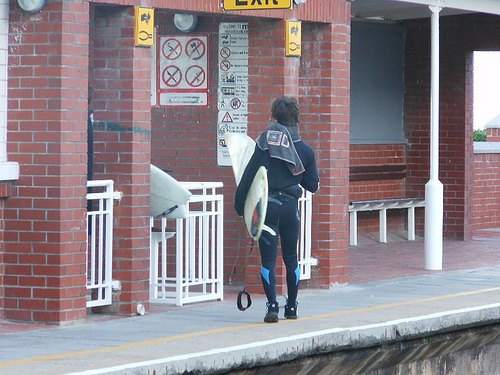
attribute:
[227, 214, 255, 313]
cord — on the surfboard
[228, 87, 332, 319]
man — next to bricks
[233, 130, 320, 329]
wetsuit — blue, black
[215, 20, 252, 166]
sign — next to bricks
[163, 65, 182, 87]
sign — next to bricks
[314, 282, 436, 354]
platform — stone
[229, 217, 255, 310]
rope — on the man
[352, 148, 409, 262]
bench — white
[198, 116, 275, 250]
surf board — with the man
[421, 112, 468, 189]
ground — next to bricks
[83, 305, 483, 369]
line — on the ground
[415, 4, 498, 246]
pillar — supporting, white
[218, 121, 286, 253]
surfboard — white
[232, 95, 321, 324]
man — standing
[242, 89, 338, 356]
wet suit — next to bricks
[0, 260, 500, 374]
pavement — on the man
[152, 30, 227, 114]
sign — next to bricks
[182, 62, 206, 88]
sign — next to bricks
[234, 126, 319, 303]
wet suit — on the man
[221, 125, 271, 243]
surfboard — white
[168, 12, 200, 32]
light — next to bricks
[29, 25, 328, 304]
wall — next to the man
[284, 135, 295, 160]
towel — around man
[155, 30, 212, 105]
placard — showing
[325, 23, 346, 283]
wall — next to the man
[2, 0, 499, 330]
building — made of bricks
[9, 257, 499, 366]
line — on the ground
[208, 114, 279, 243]
surf board — next to bricks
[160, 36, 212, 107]
sign — next to bricks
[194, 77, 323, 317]
man — young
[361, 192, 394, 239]
bench — white